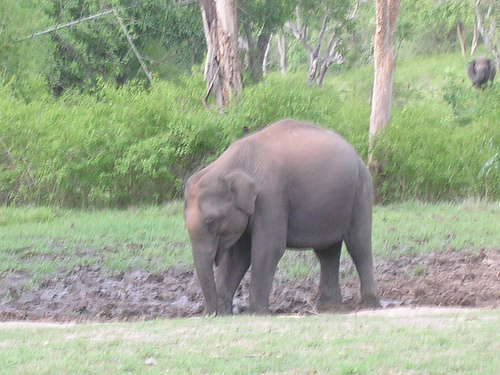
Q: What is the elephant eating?
A: Grass.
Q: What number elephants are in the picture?
A: 2.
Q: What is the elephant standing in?
A: Mud.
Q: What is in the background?
A: Bushes.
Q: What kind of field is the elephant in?
A: Grass.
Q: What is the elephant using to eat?
A: Trunk.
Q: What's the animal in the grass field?
A: Elephant.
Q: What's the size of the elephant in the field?
A: Huge.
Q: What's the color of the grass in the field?
A: Green.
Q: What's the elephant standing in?
A: Mud.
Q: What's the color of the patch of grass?
A: Green.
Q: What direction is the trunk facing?
A: Down.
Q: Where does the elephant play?
A: In mud.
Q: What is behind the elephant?
A: Tree trunk.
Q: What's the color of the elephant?
A: Grey.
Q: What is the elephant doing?
A: Playing in the mud.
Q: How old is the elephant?
A: The elephant is a young.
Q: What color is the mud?
A: The mud is brown.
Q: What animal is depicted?
A: Elephant.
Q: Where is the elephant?
A: Field.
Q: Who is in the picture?
A: No one.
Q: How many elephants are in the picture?
A: Two.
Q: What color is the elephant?
A: Gray.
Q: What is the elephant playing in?
A: Mud.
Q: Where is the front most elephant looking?
A: Down.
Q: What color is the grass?
A: Green.